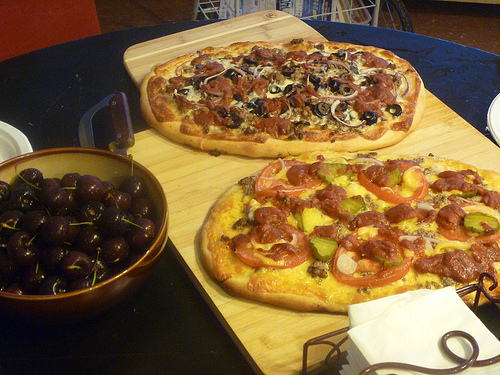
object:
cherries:
[127, 217, 154, 247]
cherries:
[99, 237, 129, 264]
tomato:
[234, 224, 314, 270]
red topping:
[354, 228, 401, 265]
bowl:
[0, 146, 169, 326]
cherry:
[80, 199, 107, 225]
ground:
[465, 20, 489, 41]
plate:
[487, 93, 500, 148]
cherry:
[103, 189, 131, 213]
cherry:
[62, 250, 92, 280]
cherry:
[76, 173, 104, 201]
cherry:
[120, 175, 147, 199]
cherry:
[11, 185, 39, 211]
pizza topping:
[376, 198, 423, 235]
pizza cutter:
[79, 91, 135, 158]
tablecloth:
[0, 20, 499, 375]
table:
[0, 19, 500, 375]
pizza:
[199, 149, 500, 313]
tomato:
[254, 160, 322, 199]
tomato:
[329, 230, 413, 288]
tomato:
[358, 162, 429, 205]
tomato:
[437, 203, 499, 244]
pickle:
[463, 211, 499, 234]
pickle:
[294, 207, 323, 234]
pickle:
[308, 236, 337, 262]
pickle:
[340, 194, 367, 215]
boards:
[123, 9, 329, 92]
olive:
[338, 103, 348, 112]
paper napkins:
[347, 287, 500, 374]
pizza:
[140, 38, 426, 160]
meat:
[353, 100, 384, 119]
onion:
[331, 100, 367, 128]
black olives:
[360, 110, 377, 126]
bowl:
[0, 120, 32, 163]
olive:
[223, 69, 237, 80]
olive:
[385, 104, 402, 117]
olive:
[317, 102, 331, 115]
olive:
[224, 113, 242, 128]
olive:
[269, 84, 281, 93]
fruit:
[42, 274, 70, 295]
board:
[107, 88, 500, 375]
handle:
[109, 91, 135, 148]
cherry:
[7, 231, 38, 266]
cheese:
[266, 156, 467, 275]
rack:
[302, 272, 500, 375]